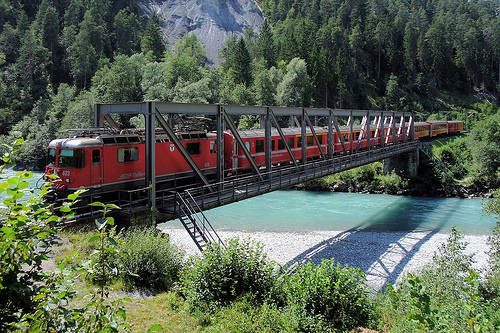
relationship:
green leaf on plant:
[88, 200, 120, 209] [86, 197, 121, 330]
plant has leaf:
[76, 195, 128, 331] [88, 199, 125, 211]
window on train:
[46, 147, 84, 168] [37, 104, 477, 212]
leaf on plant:
[366, 17, 394, 46] [354, 10, 474, 99]